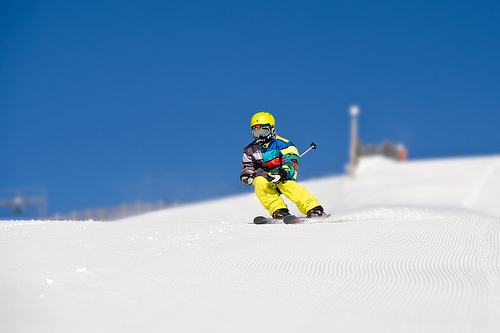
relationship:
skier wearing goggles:
[203, 88, 364, 247] [250, 124, 275, 140]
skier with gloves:
[203, 88, 364, 247] [227, 167, 287, 190]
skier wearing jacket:
[203, 88, 364, 247] [237, 140, 298, 172]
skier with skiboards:
[203, 88, 364, 247] [249, 205, 331, 231]